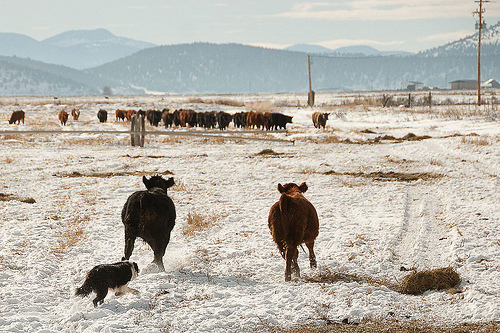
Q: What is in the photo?
A: A dog and cows.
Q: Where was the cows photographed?
A: A pasture.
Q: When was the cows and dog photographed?
A: Daytime.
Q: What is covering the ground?
A: Snow.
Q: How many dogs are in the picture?
A: One.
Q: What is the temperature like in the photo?
A: Cold.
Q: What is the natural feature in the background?
A: Mountains.